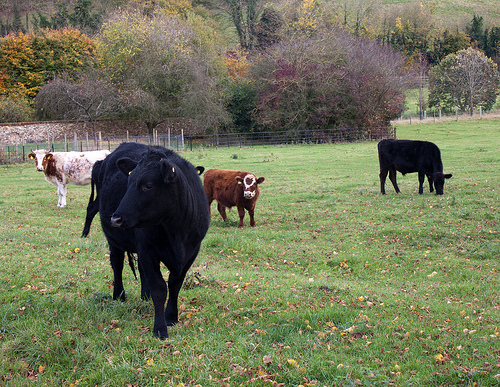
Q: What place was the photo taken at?
A: It was taken at the field.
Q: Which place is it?
A: It is a field.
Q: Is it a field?
A: Yes, it is a field.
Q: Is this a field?
A: Yes, it is a field.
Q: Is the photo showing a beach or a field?
A: It is showing a field.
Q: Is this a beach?
A: No, it is a field.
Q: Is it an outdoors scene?
A: Yes, it is outdoors.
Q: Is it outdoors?
A: Yes, it is outdoors.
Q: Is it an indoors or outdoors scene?
A: It is outdoors.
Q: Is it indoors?
A: No, it is outdoors.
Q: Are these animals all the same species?
A: Yes, all the animals are cows.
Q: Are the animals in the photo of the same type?
A: Yes, all the animals are cows.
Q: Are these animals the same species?
A: Yes, all the animals are cows.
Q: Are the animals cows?
A: Yes, all the animals are cows.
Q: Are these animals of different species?
A: No, all the animals are cows.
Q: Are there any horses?
A: No, there are no horses.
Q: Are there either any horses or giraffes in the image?
A: No, there are no horses or giraffes.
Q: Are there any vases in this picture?
A: No, there are no vases.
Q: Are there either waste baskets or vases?
A: No, there are no vases or waste baskets.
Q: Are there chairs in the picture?
A: No, there are no chairs.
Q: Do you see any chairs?
A: No, there are no chairs.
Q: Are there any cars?
A: No, there are no cars.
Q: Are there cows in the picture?
A: Yes, there is a cow.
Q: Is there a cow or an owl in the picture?
A: Yes, there is a cow.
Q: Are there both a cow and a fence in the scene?
A: Yes, there are both a cow and a fence.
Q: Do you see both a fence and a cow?
A: Yes, there are both a cow and a fence.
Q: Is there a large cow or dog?
A: Yes, there is a large cow.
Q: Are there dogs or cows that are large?
A: Yes, the cow is large.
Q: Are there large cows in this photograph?
A: Yes, there is a large cow.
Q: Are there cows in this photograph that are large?
A: Yes, there is a cow that is large.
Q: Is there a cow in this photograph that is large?
A: Yes, there is a cow that is large.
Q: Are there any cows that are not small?
A: Yes, there is a large cow.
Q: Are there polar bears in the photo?
A: No, there are no polar bears.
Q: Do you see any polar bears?
A: No, there are no polar bears.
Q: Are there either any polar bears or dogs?
A: No, there are no polar bears or dogs.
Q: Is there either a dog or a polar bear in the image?
A: No, there are no polar bears or dogs.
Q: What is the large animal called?
A: The animal is a cow.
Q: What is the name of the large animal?
A: The animal is a cow.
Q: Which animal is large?
A: The animal is a cow.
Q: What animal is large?
A: The animal is a cow.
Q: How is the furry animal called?
A: The animal is a cow.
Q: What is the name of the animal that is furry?
A: The animal is a cow.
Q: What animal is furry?
A: The animal is a cow.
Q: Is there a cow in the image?
A: Yes, there is a cow.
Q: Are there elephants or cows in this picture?
A: Yes, there is a cow.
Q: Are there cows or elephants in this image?
A: Yes, there is a cow.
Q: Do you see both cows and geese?
A: No, there is a cow but no geese.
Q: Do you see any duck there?
A: No, there are no ducks.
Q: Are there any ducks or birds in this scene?
A: No, there are no ducks or birds.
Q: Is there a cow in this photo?
A: Yes, there is a cow.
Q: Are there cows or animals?
A: Yes, there is a cow.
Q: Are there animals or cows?
A: Yes, there is a cow.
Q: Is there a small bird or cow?
A: Yes, there is a small cow.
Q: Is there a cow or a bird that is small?
A: Yes, the cow is small.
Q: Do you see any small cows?
A: Yes, there is a small cow.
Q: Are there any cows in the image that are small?
A: Yes, there is a cow that is small.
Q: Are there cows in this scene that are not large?
A: Yes, there is a small cow.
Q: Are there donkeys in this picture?
A: No, there are no donkeys.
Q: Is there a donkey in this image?
A: No, there are no donkeys.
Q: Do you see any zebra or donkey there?
A: No, there are no donkeys or zebras.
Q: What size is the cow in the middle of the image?
A: The cow is small.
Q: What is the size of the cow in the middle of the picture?
A: The cow is small.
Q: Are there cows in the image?
A: Yes, there is a cow.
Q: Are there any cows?
A: Yes, there is a cow.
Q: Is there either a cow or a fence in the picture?
A: Yes, there is a cow.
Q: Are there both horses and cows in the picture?
A: No, there is a cow but no horses.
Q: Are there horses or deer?
A: No, there are no horses or deer.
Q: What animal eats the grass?
A: The cow eats the grass.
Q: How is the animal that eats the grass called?
A: The animal is a cow.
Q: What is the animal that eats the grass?
A: The animal is a cow.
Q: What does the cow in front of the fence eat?
A: The cow eats grass.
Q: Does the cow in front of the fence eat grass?
A: Yes, the cow eats grass.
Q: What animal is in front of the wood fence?
A: The cow is in front of the fence.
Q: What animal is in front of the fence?
A: The cow is in front of the fence.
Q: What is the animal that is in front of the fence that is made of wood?
A: The animal is a cow.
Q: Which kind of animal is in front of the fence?
A: The animal is a cow.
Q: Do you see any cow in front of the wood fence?
A: Yes, there is a cow in front of the fence.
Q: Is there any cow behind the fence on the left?
A: No, the cow is in front of the fence.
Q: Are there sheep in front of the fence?
A: No, there is a cow in front of the fence.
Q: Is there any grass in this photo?
A: Yes, there is grass.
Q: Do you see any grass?
A: Yes, there is grass.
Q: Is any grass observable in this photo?
A: Yes, there is grass.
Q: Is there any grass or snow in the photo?
A: Yes, there is grass.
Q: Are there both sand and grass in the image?
A: No, there is grass but no sand.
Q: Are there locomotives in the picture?
A: No, there are no locomotives.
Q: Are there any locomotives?
A: No, there are no locomotives.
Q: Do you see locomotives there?
A: No, there are no locomotives.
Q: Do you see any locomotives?
A: No, there are no locomotives.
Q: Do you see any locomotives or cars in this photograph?
A: No, there are no locomotives or cars.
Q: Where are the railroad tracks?
A: The railroad tracks are on the hill.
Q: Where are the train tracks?
A: The railroad tracks are on the hill.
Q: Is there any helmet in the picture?
A: No, there are no helmets.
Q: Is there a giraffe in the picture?
A: No, there are no giraffes.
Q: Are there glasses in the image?
A: No, there are no glasses.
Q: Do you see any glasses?
A: No, there are no glasses.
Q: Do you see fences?
A: Yes, there is a fence.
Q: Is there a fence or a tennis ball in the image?
A: Yes, there is a fence.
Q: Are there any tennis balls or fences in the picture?
A: Yes, there is a fence.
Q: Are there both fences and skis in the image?
A: No, there is a fence but no skis.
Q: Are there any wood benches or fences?
A: Yes, there is a wood fence.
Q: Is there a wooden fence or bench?
A: Yes, there is a wood fence.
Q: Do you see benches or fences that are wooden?
A: Yes, the fence is wooden.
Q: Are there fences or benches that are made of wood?
A: Yes, the fence is made of wood.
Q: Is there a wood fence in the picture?
A: Yes, there is a wood fence.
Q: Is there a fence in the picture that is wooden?
A: Yes, there is a fence that is wooden.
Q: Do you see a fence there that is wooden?
A: Yes, there is a fence that is wooden.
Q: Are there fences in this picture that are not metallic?
A: Yes, there is a wooden fence.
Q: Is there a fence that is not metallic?
A: Yes, there is a wooden fence.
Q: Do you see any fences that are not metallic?
A: Yes, there is a wooden fence.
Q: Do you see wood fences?
A: Yes, there is a fence that is made of wood.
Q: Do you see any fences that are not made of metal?
A: Yes, there is a fence that is made of wood.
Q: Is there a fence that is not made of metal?
A: Yes, there is a fence that is made of wood.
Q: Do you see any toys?
A: No, there are no toys.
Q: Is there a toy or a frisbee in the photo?
A: No, there are no toys or frisbees.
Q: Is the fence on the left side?
A: Yes, the fence is on the left of the image.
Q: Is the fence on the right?
A: No, the fence is on the left of the image.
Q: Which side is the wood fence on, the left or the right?
A: The fence is on the left of the image.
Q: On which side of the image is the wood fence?
A: The fence is on the left of the image.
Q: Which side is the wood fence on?
A: The fence is on the left of the image.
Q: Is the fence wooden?
A: Yes, the fence is wooden.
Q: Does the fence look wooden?
A: Yes, the fence is wooden.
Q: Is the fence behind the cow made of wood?
A: Yes, the fence is made of wood.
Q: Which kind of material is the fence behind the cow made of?
A: The fence is made of wood.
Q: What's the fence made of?
A: The fence is made of wood.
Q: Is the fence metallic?
A: No, the fence is wooden.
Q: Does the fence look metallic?
A: No, the fence is wooden.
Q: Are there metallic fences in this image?
A: No, there is a fence but it is wooden.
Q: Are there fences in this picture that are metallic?
A: No, there is a fence but it is wooden.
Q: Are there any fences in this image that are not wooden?
A: No, there is a fence but it is wooden.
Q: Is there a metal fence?
A: No, there is a fence but it is made of wood.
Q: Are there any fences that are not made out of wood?
A: No, there is a fence but it is made of wood.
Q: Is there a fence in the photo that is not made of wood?
A: No, there is a fence but it is made of wood.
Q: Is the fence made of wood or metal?
A: The fence is made of wood.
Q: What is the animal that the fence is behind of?
A: The animal is a cow.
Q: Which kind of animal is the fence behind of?
A: The fence is behind the cow.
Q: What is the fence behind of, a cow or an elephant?
A: The fence is behind a cow.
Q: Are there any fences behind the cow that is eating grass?
A: Yes, there is a fence behind the cow.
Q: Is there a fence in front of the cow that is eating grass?
A: No, the fence is behind the cow.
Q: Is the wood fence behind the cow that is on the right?
A: Yes, the fence is behind the cow.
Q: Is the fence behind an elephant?
A: No, the fence is behind the cow.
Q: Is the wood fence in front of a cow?
A: No, the fence is behind a cow.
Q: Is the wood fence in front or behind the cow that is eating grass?
A: The fence is behind the cow.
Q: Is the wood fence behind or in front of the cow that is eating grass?
A: The fence is behind the cow.